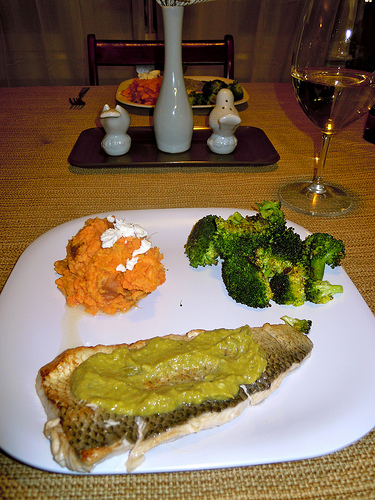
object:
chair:
[75, 29, 247, 79]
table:
[4, 70, 373, 500]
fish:
[31, 320, 316, 475]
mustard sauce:
[78, 382, 88, 394]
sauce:
[209, 342, 219, 355]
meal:
[36, 193, 348, 478]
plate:
[0, 208, 373, 474]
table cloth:
[19, 132, 57, 214]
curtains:
[0, 5, 339, 83]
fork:
[66, 85, 91, 108]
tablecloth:
[351, 219, 371, 281]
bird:
[205, 85, 250, 178]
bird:
[208, 88, 242, 154]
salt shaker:
[207, 88, 242, 155]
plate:
[114, 73, 250, 108]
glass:
[277, 2, 375, 217]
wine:
[290, 69, 375, 132]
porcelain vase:
[153, 5, 194, 155]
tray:
[66, 123, 280, 169]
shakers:
[98, 104, 131, 157]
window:
[0, 4, 308, 85]